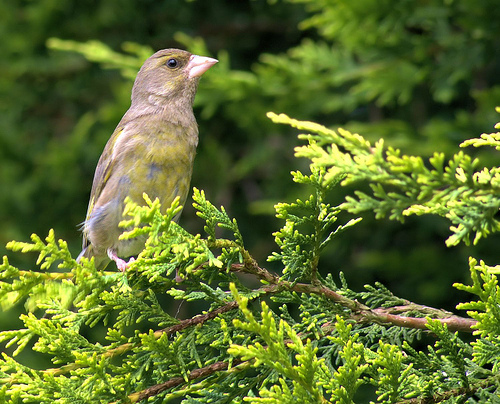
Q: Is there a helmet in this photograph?
A: No, there are no helmets.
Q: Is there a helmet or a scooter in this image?
A: No, there are no helmets or scooters.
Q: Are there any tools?
A: No, there are no tools.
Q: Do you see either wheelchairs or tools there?
A: No, there are no tools or wheelchairs.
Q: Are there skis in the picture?
A: No, there are no skis.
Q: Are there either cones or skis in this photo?
A: No, there are no skis or cones.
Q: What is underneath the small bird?
A: The branch is underneath the bird.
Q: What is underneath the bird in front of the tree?
A: The branch is underneath the bird.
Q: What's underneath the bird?
A: The branch is underneath the bird.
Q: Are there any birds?
A: Yes, there is a bird.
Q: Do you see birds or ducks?
A: Yes, there is a bird.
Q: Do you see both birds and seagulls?
A: No, there is a bird but no seagulls.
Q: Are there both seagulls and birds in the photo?
A: No, there is a bird but no seagulls.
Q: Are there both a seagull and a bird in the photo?
A: No, there is a bird but no seagulls.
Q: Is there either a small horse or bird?
A: Yes, there is a small bird.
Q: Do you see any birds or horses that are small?
A: Yes, the bird is small.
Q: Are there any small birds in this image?
A: Yes, there is a small bird.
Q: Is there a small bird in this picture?
A: Yes, there is a small bird.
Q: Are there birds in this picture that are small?
A: Yes, there is a bird that is small.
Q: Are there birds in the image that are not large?
A: Yes, there is a small bird.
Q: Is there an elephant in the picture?
A: No, there are no elephants.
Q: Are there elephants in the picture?
A: No, there are no elephants.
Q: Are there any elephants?
A: No, there are no elephants.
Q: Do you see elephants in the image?
A: No, there are no elephants.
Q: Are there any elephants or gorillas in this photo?
A: No, there are no elephants or gorillas.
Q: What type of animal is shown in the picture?
A: The animal is a bird.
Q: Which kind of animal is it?
A: The animal is a bird.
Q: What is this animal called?
A: This is a bird.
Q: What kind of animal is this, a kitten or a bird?
A: This is a bird.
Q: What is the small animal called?
A: The animal is a bird.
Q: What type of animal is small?
A: The animal is a bird.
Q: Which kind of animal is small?
A: The animal is a bird.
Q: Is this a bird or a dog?
A: This is a bird.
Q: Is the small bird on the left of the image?
A: Yes, the bird is on the left of the image.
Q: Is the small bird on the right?
A: No, the bird is on the left of the image.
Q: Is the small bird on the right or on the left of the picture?
A: The bird is on the left of the image.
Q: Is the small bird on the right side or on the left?
A: The bird is on the left of the image.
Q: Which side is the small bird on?
A: The bird is on the left of the image.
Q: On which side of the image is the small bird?
A: The bird is on the left of the image.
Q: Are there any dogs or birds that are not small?
A: No, there is a bird but it is small.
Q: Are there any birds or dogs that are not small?
A: No, there is a bird but it is small.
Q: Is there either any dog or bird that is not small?
A: No, there is a bird but it is small.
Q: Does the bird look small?
A: Yes, the bird is small.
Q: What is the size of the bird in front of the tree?
A: The bird is small.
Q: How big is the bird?
A: The bird is small.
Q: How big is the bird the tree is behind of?
A: The bird is small.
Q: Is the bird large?
A: No, the bird is small.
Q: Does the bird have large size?
A: No, the bird is small.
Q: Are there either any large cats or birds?
A: No, there is a bird but it is small.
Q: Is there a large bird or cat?
A: No, there is a bird but it is small.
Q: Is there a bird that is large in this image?
A: No, there is a bird but it is small.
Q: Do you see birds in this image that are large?
A: No, there is a bird but it is small.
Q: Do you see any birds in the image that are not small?
A: No, there is a bird but it is small.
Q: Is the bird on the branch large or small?
A: The bird is small.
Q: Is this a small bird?
A: Yes, this is a small bird.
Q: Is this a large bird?
A: No, this is a small bird.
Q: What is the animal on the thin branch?
A: The animal is a bird.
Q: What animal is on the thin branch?
A: The animal is a bird.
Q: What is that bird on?
A: The bird is on the branch.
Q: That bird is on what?
A: The bird is on the branch.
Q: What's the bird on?
A: The bird is on the branch.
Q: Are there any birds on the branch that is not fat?
A: Yes, there is a bird on the branch.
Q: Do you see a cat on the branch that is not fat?
A: No, there is a bird on the branch.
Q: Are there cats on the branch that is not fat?
A: No, there is a bird on the branch.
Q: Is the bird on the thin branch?
A: Yes, the bird is on the branch.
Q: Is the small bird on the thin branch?
A: Yes, the bird is on the branch.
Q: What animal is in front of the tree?
A: The bird is in front of the tree.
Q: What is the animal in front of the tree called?
A: The animal is a bird.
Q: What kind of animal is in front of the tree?
A: The animal is a bird.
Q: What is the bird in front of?
A: The bird is in front of the tree.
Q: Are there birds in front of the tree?
A: Yes, there is a bird in front of the tree.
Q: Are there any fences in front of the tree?
A: No, there is a bird in front of the tree.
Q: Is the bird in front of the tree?
A: Yes, the bird is in front of the tree.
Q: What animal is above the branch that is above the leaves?
A: The animal is a bird.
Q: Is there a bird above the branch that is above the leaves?
A: Yes, there is a bird above the branch.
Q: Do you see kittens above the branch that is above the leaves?
A: No, there is a bird above the branch.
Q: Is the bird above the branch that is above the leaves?
A: Yes, the bird is above the branch.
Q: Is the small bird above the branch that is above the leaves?
A: Yes, the bird is above the branch.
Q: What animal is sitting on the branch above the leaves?
A: The bird is sitting on the branch.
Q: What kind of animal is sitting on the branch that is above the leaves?
A: The animal is a bird.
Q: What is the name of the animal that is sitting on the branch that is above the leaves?
A: The animal is a bird.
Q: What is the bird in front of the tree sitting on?
A: The bird is sitting on the branch.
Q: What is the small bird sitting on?
A: The bird is sitting on the branch.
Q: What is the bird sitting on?
A: The bird is sitting on the branch.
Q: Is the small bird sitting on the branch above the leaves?
A: Yes, the bird is sitting on the branch.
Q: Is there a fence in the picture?
A: No, there are no fences.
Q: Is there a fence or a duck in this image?
A: No, there are no fences or ducks.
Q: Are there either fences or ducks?
A: No, there are no fences or ducks.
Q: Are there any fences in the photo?
A: No, there are no fences.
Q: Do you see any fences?
A: No, there are no fences.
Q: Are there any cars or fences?
A: No, there are no fences or cars.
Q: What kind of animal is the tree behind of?
A: The tree is behind the bird.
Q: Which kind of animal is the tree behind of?
A: The tree is behind the bird.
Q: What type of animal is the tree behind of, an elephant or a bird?
A: The tree is behind a bird.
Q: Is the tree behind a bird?
A: Yes, the tree is behind a bird.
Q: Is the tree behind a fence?
A: No, the tree is behind a bird.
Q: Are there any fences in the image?
A: No, there are no fences.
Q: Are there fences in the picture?
A: No, there are no fences.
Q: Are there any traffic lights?
A: No, there are no traffic lights.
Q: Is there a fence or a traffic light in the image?
A: No, there are no traffic lights or fences.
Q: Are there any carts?
A: No, there are no carts.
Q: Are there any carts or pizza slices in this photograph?
A: No, there are no carts or pizza slices.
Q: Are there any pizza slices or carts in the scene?
A: No, there are no carts or pizza slices.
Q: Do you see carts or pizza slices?
A: No, there are no carts or pizza slices.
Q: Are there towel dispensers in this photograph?
A: No, there are no towel dispensers.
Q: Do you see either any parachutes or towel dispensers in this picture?
A: No, there are no towel dispensers or parachutes.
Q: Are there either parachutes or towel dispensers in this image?
A: No, there are no towel dispensers or parachutes.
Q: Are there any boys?
A: No, there are no boys.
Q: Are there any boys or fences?
A: No, there are no boys or fences.